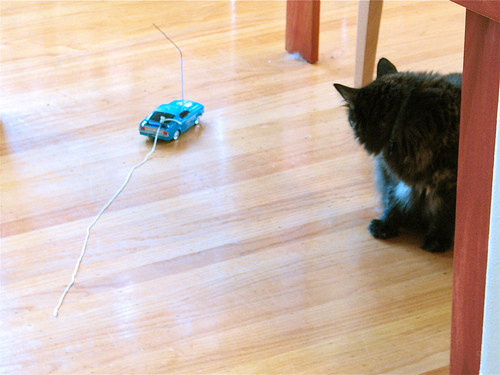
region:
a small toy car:
[106, 20, 223, 175]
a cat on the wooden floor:
[320, 30, 480, 280]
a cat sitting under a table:
[330, 45, 490, 275]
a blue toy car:
[136, 88, 226, 150]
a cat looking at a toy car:
[293, 57, 494, 269]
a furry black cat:
[315, 30, 470, 265]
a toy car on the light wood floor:
[13, 10, 331, 373]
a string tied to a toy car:
[36, 113, 162, 320]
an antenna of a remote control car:
[148, 15, 190, 115]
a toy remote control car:
[131, 20, 250, 168]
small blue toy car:
[134, 96, 207, 144]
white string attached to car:
[53, 117, 185, 334]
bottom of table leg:
[281, 2, 330, 65]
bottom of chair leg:
[348, 0, 383, 89]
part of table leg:
[444, 0, 499, 374]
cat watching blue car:
[136, 53, 461, 264]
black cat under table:
[328, 9, 498, 374]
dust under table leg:
[276, 47, 311, 65]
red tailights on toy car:
[138, 123, 170, 138]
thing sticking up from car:
[148, 19, 188, 116]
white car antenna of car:
[149, 22, 186, 107]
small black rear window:
[149, 109, 176, 130]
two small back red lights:
[138, 125, 170, 140]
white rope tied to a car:
[50, 115, 170, 318]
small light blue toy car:
[140, 97, 207, 143]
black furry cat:
[333, 50, 482, 255]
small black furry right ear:
[373, 56, 395, 77]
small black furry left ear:
[331, 81, 362, 103]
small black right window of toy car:
[181, 108, 189, 122]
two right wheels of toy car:
[170, 116, 200, 141]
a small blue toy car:
[140, 95, 205, 142]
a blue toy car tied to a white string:
[13, 95, 203, 373]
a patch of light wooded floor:
[111, 203, 353, 374]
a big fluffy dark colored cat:
[331, 55, 465, 256]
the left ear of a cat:
[332, 82, 359, 104]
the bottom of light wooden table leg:
[282, 0, 323, 62]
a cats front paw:
[368, 210, 399, 244]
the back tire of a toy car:
[173, 129, 181, 139]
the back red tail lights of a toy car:
[138, 125, 168, 137]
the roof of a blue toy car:
[156, 102, 186, 117]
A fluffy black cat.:
[333, 58, 461, 255]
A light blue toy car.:
[137, 23, 205, 141]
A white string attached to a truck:
[50, 113, 182, 317]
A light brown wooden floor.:
[0, 0, 465, 373]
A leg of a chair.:
[355, 0, 383, 91]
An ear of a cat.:
[333, 82, 365, 109]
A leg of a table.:
[284, 0, 321, 63]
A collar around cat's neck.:
[386, 79, 416, 157]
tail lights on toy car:
[137, 125, 168, 135]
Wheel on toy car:
[170, 129, 181, 139]